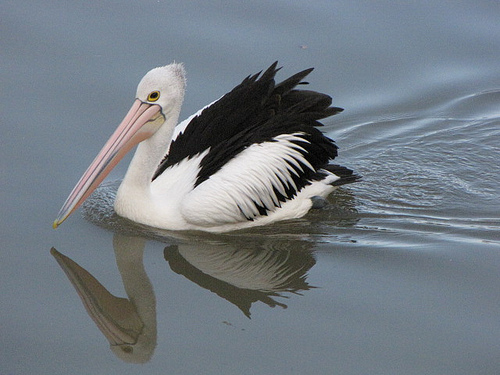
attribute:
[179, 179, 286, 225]
white feathers — pelican's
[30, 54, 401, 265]
bird — black-and-white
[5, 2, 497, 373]
water — dead-calm, calm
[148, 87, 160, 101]
eye — one, avian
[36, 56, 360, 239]
bird — one, black-and-white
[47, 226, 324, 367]
reflection — pelican's, clearly visible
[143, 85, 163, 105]
yellow eyes — gentle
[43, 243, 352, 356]
water — clear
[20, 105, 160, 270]
beak — pelican's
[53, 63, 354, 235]
pelican — pelican's, beautiful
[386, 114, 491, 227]
wave — small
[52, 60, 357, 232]
duck — one, black, white, wet, swimming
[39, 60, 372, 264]
bird — black-and-white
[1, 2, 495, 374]
bird — black-and-white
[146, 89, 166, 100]
eye — one, avian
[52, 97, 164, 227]
beak — pink, blue-edged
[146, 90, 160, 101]
eye — bird's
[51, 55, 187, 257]
head — one, avian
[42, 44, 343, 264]
bird — one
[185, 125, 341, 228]
wind — black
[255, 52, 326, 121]
feather — bird's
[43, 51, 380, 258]
bird — black-and-white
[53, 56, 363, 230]
bird — black-and-white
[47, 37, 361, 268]
bird — white, black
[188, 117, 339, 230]
wing — white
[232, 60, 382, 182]
tail — bird tail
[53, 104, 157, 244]
beak — pink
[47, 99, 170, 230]
beak — pink